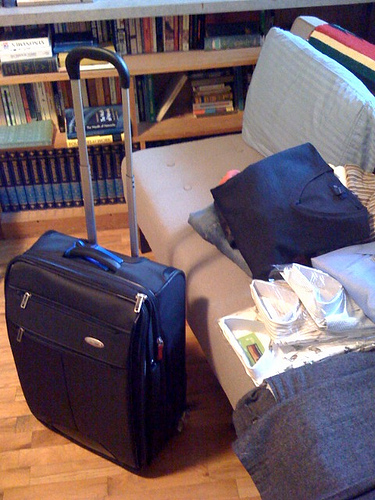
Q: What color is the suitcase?
A: Black.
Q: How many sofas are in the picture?
A: One.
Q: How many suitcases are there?
A: One.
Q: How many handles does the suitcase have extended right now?
A: One.